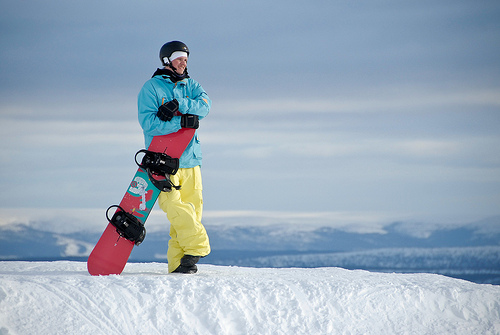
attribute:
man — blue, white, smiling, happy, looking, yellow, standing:
[127, 29, 221, 281]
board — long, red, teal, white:
[89, 112, 199, 281]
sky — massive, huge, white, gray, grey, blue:
[4, 0, 492, 273]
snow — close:
[2, 255, 497, 333]